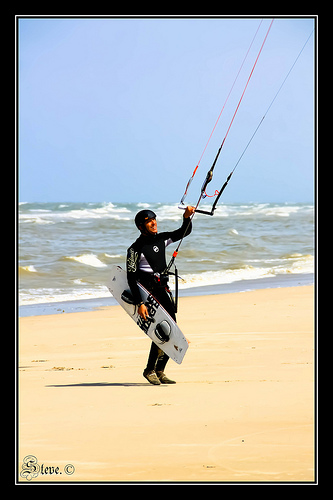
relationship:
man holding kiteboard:
[124, 204, 198, 389] [102, 262, 190, 368]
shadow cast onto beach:
[42, 379, 165, 393] [18, 282, 315, 484]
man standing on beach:
[124, 204, 198, 389] [18, 282, 315, 484]